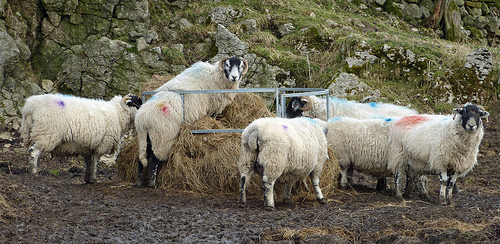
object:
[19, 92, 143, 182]
sheep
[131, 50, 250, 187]
sheep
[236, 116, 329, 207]
sheep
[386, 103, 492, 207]
sheep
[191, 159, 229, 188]
hay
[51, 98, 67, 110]
dot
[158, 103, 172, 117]
dot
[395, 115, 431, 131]
dot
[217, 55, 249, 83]
face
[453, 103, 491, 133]
face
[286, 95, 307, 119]
face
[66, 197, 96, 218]
dirt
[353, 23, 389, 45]
grass